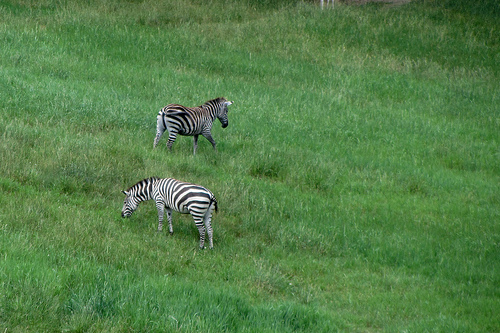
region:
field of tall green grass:
[260, 31, 491, 174]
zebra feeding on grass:
[110, 161, 235, 256]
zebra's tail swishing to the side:
[160, 105, 195, 117]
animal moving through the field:
[141, 70, 256, 160]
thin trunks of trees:
[305, 0, 337, 16]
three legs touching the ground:
[145, 137, 221, 153]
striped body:
[170, 181, 206, 206]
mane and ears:
[201, 92, 231, 107]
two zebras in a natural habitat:
[92, 80, 282, 267]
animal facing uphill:
[55, 150, 370, 325]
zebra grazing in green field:
[100, 166, 248, 271]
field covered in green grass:
[352, 80, 483, 159]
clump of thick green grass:
[233, 143, 365, 199]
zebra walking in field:
[118, 75, 273, 157]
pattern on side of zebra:
[166, 189, 198, 204]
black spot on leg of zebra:
[164, 206, 179, 223]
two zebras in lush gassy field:
[23, 42, 380, 323]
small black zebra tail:
[209, 195, 226, 219]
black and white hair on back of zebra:
[129, 170, 159, 190]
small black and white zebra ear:
[115, 186, 134, 205]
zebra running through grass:
[141, 88, 246, 150]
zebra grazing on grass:
[103, 175, 225, 242]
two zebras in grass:
[116, 89, 240, 244]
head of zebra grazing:
[107, 183, 144, 223]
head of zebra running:
[212, 97, 232, 130]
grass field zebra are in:
[7, 11, 485, 318]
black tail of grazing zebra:
[207, 199, 222, 213]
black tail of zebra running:
[160, 115, 170, 133]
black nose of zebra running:
[220, 119, 232, 127]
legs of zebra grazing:
[149, 200, 217, 249]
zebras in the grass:
[58, 44, 395, 301]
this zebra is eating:
[110, 167, 227, 257]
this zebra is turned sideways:
[113, 174, 221, 255]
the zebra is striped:
[109, 175, 221, 250]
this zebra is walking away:
[140, 91, 240, 158]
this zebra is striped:
[137, 84, 233, 162]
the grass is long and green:
[2, 4, 487, 330]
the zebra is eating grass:
[102, 169, 223, 261]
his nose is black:
[220, 118, 232, 129]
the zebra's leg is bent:
[204, 131, 221, 157]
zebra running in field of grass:
[141, 89, 236, 152]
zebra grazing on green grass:
[107, 169, 221, 245]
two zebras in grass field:
[95, 69, 249, 246]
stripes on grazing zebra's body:
[125, 181, 210, 232]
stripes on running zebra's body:
[155, 105, 218, 140]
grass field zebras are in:
[15, 10, 480, 327]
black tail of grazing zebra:
[210, 195, 225, 218]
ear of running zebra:
[222, 93, 235, 108]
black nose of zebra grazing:
[118, 210, 127, 220]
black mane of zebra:
[122, 175, 160, 187]